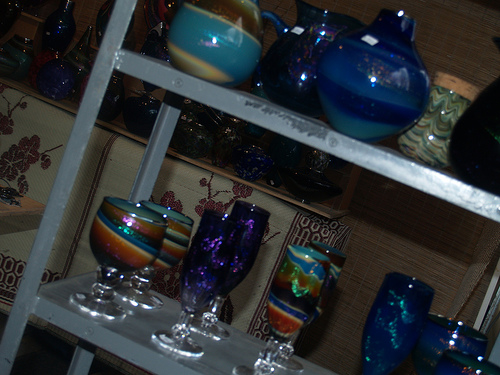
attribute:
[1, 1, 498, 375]
unit — full, gray, metal, angled, shelving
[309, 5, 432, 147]
vase — dark blue, light blue, shiny blue, small, dark, light colored, blue, glass, blown glass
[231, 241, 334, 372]
goblets — multicolored, for sale, multi-colored, wine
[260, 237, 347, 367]
goblets — striped, for sale, multi-colored, colorful, wine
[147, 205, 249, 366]
glasses — blue, purple, tall, skinny, bright blue, blue crystal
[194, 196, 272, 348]
glasses — blue, purple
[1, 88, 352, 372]
tapestry — floral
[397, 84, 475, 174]
glass — designed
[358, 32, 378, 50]
sticker — white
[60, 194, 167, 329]
glasses — smaller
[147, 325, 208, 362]
bottom — clear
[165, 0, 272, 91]
glass — tan, blue, brown, round, swirly